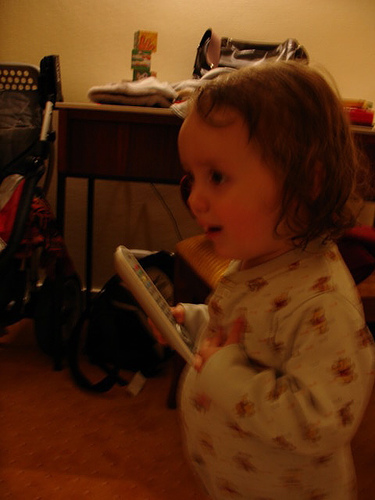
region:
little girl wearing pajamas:
[176, 66, 372, 498]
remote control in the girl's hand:
[114, 246, 200, 366]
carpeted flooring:
[0, 394, 166, 497]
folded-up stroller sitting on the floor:
[0, 50, 72, 384]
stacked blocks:
[132, 28, 156, 84]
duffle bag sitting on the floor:
[73, 248, 176, 421]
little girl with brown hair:
[175, 59, 356, 498]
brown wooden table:
[54, 99, 177, 190]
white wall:
[3, 0, 374, 27]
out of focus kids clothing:
[175, 257, 367, 495]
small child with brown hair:
[100, 57, 371, 498]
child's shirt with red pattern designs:
[160, 240, 373, 498]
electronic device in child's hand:
[106, 239, 207, 369]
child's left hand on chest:
[178, 310, 261, 387]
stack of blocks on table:
[125, 22, 165, 88]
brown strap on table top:
[188, 25, 226, 79]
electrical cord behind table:
[144, 178, 189, 247]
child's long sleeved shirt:
[171, 232, 371, 499]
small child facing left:
[108, 47, 369, 499]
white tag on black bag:
[119, 366, 149, 402]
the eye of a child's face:
[185, 170, 195, 181]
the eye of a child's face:
[208, 169, 227, 185]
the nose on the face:
[189, 174, 207, 209]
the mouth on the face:
[196, 218, 223, 236]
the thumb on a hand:
[226, 317, 246, 343]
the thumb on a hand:
[169, 304, 183, 316]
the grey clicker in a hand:
[114, 243, 195, 359]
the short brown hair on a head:
[194, 56, 357, 243]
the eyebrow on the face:
[180, 159, 190, 168]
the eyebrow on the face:
[198, 156, 220, 168]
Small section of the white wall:
[286, 7, 307, 29]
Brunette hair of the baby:
[293, 86, 325, 120]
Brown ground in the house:
[82, 441, 112, 465]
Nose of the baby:
[188, 193, 207, 212]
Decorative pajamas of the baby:
[192, 403, 227, 445]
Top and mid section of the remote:
[112, 245, 174, 321]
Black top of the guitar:
[39, 55, 65, 105]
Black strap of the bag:
[72, 359, 106, 393]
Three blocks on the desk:
[129, 29, 159, 79]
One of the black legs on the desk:
[83, 179, 96, 290]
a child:
[179, 64, 365, 496]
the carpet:
[82, 433, 155, 478]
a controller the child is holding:
[107, 242, 193, 357]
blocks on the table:
[123, 25, 162, 71]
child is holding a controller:
[135, 313, 186, 347]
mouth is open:
[200, 220, 222, 238]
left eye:
[201, 168, 231, 186]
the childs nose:
[183, 189, 205, 214]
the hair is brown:
[281, 133, 321, 168]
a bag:
[86, 309, 147, 363]